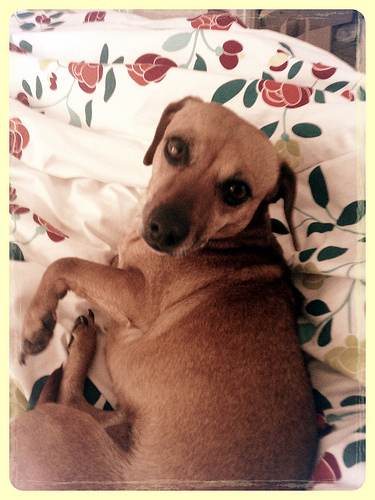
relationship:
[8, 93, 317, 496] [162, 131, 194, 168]
dog has eye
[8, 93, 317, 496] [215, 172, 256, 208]
dog has eye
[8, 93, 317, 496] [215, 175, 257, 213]
dog has eye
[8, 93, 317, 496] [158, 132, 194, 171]
dog has eye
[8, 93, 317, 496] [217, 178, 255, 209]
dog has eye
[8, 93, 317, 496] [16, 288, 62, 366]
dog has paw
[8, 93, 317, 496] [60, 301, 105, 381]
dog has paw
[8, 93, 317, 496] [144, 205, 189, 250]
dog has nose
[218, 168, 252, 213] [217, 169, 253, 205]
ring encircling eye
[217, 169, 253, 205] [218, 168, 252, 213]
eye inside of ring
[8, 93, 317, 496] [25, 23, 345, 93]
dog on top of blanket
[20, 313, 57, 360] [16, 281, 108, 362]
pads are attached to feet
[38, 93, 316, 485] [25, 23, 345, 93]
dog on top of blanket